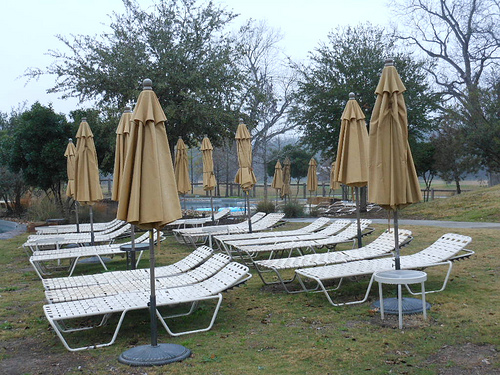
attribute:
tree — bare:
[409, 20, 494, 132]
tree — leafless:
[282, 17, 441, 197]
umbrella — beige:
[365, 55, 432, 215]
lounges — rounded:
[23, 207, 482, 360]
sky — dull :
[0, 0, 498, 136]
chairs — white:
[18, 204, 479, 354]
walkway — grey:
[425, 216, 487, 234]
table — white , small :
[375, 269, 427, 329]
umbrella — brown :
[115, 74, 183, 228]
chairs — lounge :
[297, 232, 486, 303]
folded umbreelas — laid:
[52, 60, 429, 249]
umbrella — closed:
[118, 76, 180, 224]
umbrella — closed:
[367, 55, 422, 210]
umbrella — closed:
[332, 89, 370, 185]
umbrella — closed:
[72, 117, 103, 205]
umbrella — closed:
[230, 117, 257, 186]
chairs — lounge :
[11, 202, 294, 374]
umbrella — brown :
[360, 55, 428, 215]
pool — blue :
[198, 207, 254, 210]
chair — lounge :
[38, 260, 256, 350]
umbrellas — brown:
[326, 53, 429, 211]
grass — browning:
[11, 246, 474, 355]